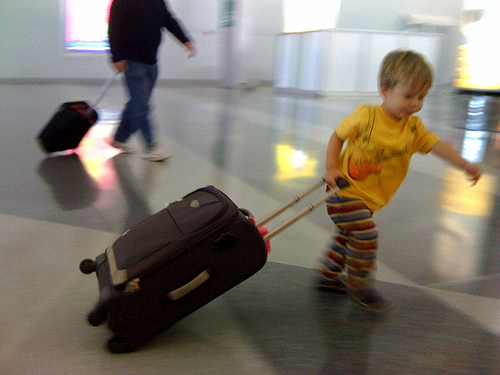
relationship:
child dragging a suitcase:
[309, 44, 485, 308] [68, 171, 350, 358]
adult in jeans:
[101, 2, 201, 166] [110, 62, 164, 149]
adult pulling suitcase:
[101, 2, 201, 166] [34, 65, 127, 157]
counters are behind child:
[267, 26, 445, 109] [309, 44, 485, 308]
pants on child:
[317, 184, 384, 295] [309, 44, 485, 308]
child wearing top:
[309, 44, 485, 308] [323, 98, 440, 209]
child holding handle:
[309, 44, 485, 308] [319, 172, 351, 192]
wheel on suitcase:
[102, 336, 125, 355] [68, 171, 350, 358]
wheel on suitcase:
[86, 312, 111, 330] [68, 171, 350, 358]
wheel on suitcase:
[77, 257, 100, 275] [68, 171, 350, 358]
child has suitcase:
[309, 44, 485, 308] [68, 171, 350, 358]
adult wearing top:
[101, 2, 201, 166] [105, 1, 194, 67]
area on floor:
[272, 143, 319, 184] [1, 80, 500, 374]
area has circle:
[272, 143, 319, 184] [289, 150, 308, 170]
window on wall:
[60, 2, 117, 58] [1, 2, 225, 83]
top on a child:
[323, 98, 440, 209] [309, 44, 485, 308]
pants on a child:
[317, 184, 384, 295] [309, 44, 485, 308]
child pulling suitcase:
[309, 44, 485, 308] [68, 171, 350, 358]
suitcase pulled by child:
[68, 171, 350, 358] [309, 44, 485, 308]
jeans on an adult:
[110, 62, 164, 149] [101, 2, 201, 166]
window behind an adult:
[60, 2, 117, 58] [101, 2, 201, 166]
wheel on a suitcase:
[102, 336, 125, 355] [68, 171, 350, 358]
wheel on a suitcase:
[86, 312, 111, 330] [68, 171, 350, 358]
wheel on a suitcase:
[77, 257, 100, 275] [68, 171, 350, 358]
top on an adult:
[105, 1, 194, 67] [101, 2, 201, 166]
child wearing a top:
[309, 44, 485, 308] [323, 98, 440, 209]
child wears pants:
[309, 44, 485, 308] [317, 184, 384, 295]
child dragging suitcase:
[309, 44, 485, 308] [68, 171, 350, 358]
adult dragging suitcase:
[101, 2, 201, 166] [34, 65, 127, 157]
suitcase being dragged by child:
[68, 171, 350, 358] [309, 44, 485, 308]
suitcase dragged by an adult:
[34, 65, 127, 157] [101, 2, 201, 166]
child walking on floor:
[309, 44, 485, 308] [1, 80, 500, 374]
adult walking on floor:
[101, 2, 201, 166] [1, 80, 500, 374]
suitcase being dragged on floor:
[68, 171, 350, 358] [1, 80, 500, 374]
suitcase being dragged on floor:
[34, 65, 127, 157] [1, 80, 500, 374]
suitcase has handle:
[68, 171, 350, 358] [319, 172, 351, 192]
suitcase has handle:
[34, 65, 127, 157] [107, 65, 124, 80]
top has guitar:
[323, 98, 440, 209] [347, 147, 410, 183]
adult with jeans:
[101, 2, 201, 166] [110, 62, 164, 149]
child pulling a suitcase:
[309, 44, 485, 308] [68, 171, 350, 358]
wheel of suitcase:
[86, 312, 111, 330] [68, 171, 350, 358]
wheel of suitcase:
[77, 257, 100, 275] [68, 171, 350, 358]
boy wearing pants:
[309, 44, 485, 308] [317, 184, 384, 295]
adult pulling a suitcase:
[101, 2, 201, 166] [34, 65, 127, 157]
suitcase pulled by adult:
[34, 65, 127, 157] [101, 2, 201, 166]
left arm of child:
[418, 123, 490, 186] [309, 44, 485, 308]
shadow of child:
[306, 276, 382, 375] [309, 44, 485, 308]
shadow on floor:
[306, 276, 382, 375] [1, 80, 500, 374]